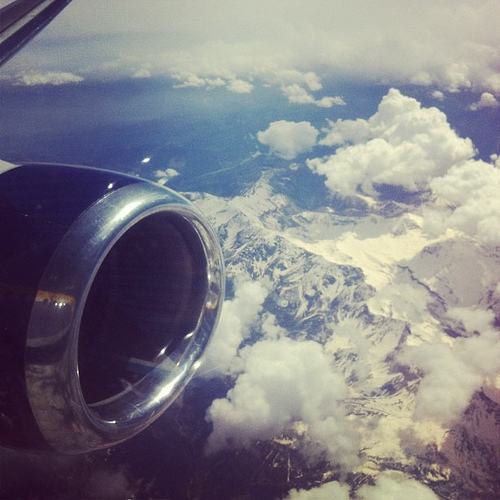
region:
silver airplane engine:
[1, 153, 218, 463]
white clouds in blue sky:
[72, 23, 160, 88]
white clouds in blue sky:
[217, 105, 321, 172]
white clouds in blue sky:
[259, 302, 333, 393]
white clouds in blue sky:
[242, 369, 326, 439]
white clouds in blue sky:
[332, 342, 400, 422]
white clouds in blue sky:
[360, 166, 445, 270]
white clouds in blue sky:
[270, 11, 342, 86]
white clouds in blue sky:
[349, 59, 450, 146]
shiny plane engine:
[13, 167, 220, 453]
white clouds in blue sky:
[65, 26, 157, 100]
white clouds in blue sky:
[347, 238, 422, 323]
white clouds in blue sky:
[367, 351, 441, 449]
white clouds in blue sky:
[320, 88, 396, 153]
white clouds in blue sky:
[278, 30, 378, 108]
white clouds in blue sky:
[131, 26, 172, 66]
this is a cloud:
[227, 349, 351, 441]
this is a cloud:
[293, 472, 349, 497]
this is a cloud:
[331, 95, 461, 189]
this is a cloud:
[260, 118, 322, 166]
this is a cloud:
[420, 212, 498, 314]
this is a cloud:
[392, 330, 480, 427]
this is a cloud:
[445, 153, 497, 245]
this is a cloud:
[240, 36, 350, 106]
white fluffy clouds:
[330, 101, 463, 192]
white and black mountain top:
[238, 199, 370, 324]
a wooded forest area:
[68, 76, 290, 151]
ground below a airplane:
[18, 0, 491, 492]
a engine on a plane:
[7, 155, 224, 465]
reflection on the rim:
[131, 330, 206, 411]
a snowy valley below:
[345, 220, 427, 276]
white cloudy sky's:
[60, 0, 490, 65]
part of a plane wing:
[5, 0, 65, 80]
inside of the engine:
[108, 252, 161, 353]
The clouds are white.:
[263, 108, 464, 196]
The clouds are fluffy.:
[273, 117, 474, 205]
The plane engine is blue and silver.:
[6, 168, 225, 454]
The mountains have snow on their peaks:
[269, 252, 362, 309]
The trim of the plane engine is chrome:
[39, 300, 68, 392]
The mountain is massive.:
[258, 220, 411, 350]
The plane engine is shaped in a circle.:
[43, 179, 233, 462]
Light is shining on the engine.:
[85, 181, 171, 214]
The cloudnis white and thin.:
[241, 350, 357, 455]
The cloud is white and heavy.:
[104, 17, 401, 68]